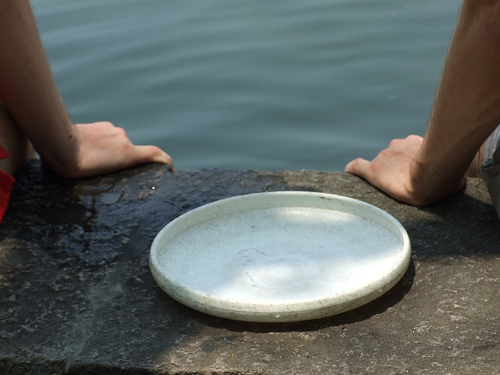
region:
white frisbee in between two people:
[142, 185, 418, 320]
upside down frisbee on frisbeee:
[142, 178, 422, 333]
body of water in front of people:
[40, 5, 445, 127]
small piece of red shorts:
[1, 137, 22, 227]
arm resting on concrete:
[0, 0, 191, 177]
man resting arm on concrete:
[395, 6, 493, 202]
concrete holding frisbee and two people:
[0, 152, 496, 367]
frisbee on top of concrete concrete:
[27, 156, 413, 371]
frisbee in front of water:
[145, 175, 412, 330]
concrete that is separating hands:
[112, 130, 387, 190]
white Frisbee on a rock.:
[137, 188, 443, 335]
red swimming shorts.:
[0, 136, 20, 228]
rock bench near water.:
[206, 101, 296, 191]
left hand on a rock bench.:
[325, 110, 490, 222]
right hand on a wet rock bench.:
[51, 75, 161, 205]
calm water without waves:
[201, 71, 301, 141]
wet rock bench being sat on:
[21, 191, 143, 296]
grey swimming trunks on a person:
[461, 131, 496, 181]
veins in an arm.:
[451, 95, 491, 175]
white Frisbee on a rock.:
[152, 205, 302, 325]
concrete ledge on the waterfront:
[1, 172, 495, 372]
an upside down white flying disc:
[145, 187, 416, 331]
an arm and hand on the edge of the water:
[3, 2, 176, 164]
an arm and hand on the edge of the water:
[342, 0, 499, 209]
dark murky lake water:
[33, 1, 459, 167]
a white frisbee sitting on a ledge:
[147, 186, 412, 326]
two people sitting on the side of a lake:
[0, 0, 498, 190]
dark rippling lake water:
[0, 4, 496, 160]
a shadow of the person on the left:
[9, 197, 498, 372]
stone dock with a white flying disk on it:
[5, 170, 496, 374]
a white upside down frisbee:
[143, 174, 414, 328]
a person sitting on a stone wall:
[359, 11, 498, 215]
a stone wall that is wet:
[67, 141, 187, 312]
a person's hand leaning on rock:
[37, 107, 175, 184]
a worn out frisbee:
[144, 182, 415, 325]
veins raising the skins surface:
[406, 109, 498, 197]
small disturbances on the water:
[117, 17, 378, 128]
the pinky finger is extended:
[77, 107, 184, 182]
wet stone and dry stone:
[216, 79, 336, 189]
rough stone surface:
[418, 249, 490, 359]